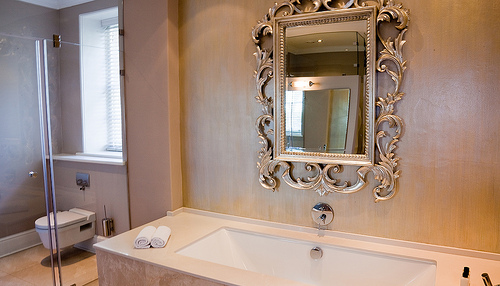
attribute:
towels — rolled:
[132, 223, 172, 248]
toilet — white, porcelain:
[34, 205, 97, 259]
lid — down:
[31, 207, 87, 230]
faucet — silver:
[303, 193, 338, 243]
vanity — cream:
[89, 203, 494, 283]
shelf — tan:
[93, 214, 498, 281]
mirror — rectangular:
[264, 12, 398, 171]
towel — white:
[148, 223, 171, 246]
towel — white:
[132, 223, 155, 248]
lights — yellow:
[292, 80, 318, 89]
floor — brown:
[26, 239, 107, 271]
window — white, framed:
[78, 9, 128, 159]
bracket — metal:
[52, 32, 62, 47]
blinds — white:
[96, 13, 123, 153]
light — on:
[291, 77, 307, 87]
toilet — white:
[34, 203, 94, 248]